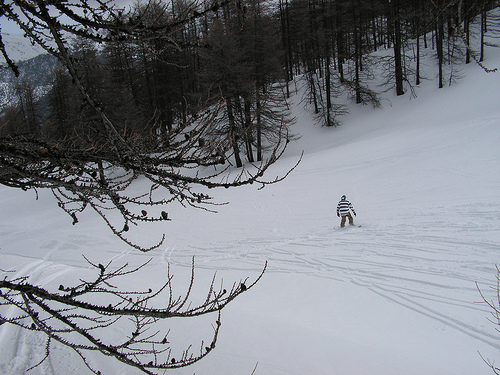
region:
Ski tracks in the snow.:
[268, 243, 438, 310]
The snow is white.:
[251, 284, 400, 356]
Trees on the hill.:
[183, 8, 390, 96]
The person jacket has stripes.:
[335, 203, 362, 219]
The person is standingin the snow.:
[319, 184, 386, 250]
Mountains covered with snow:
[4, 20, 97, 89]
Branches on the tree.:
[43, 256, 245, 365]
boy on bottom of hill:
[328, 193, 353, 235]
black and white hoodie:
[328, 197, 351, 218]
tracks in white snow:
[278, 223, 400, 287]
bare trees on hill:
[200, 32, 454, 152]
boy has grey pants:
[319, 218, 372, 235]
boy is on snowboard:
[334, 225, 364, 235]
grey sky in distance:
[3, 3, 50, 45]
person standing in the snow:
[331, 193, 357, 228]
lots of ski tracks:
[6, 201, 498, 371]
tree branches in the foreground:
[4, 3, 304, 374]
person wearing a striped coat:
[335, 192, 358, 232]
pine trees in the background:
[6, 5, 499, 173]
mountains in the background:
[1, 26, 160, 110]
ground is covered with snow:
[3, 28, 497, 373]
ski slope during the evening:
[4, 3, 498, 373]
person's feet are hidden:
[329, 218, 365, 233]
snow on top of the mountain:
[0, 26, 73, 63]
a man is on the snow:
[333, 192, 358, 227]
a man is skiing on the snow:
[332, 192, 369, 230]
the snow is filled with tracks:
[119, 203, 483, 328]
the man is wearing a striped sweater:
[337, 198, 355, 213]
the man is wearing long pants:
[339, 213, 355, 227]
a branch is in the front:
[4, 248, 266, 363]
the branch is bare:
[1, 242, 268, 368]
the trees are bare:
[1, 2, 496, 217]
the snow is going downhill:
[12, 33, 496, 373]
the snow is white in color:
[8, 45, 496, 367]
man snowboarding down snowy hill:
[332, 190, 362, 228]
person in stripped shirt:
[338, 190, 365, 222]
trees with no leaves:
[92, 19, 403, 106]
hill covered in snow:
[235, 225, 460, 340]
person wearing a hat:
[334, 194, 362, 224]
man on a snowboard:
[333, 198, 388, 225]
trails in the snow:
[273, 240, 463, 309]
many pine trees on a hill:
[122, 17, 452, 125]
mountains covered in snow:
[9, 30, 182, 150]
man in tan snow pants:
[333, 193, 375, 230]